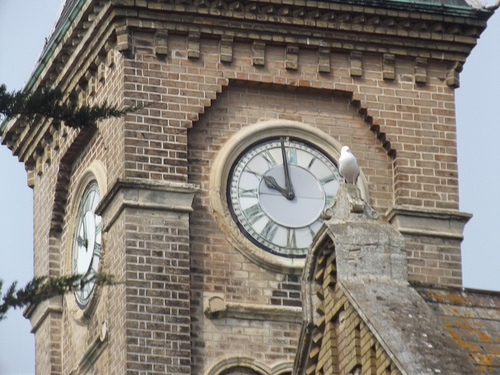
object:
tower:
[3, 0, 500, 375]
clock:
[209, 120, 365, 276]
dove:
[338, 146, 362, 184]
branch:
[0, 83, 155, 129]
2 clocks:
[60, 117, 368, 322]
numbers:
[261, 221, 279, 241]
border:
[1, 0, 101, 124]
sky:
[0, 0, 500, 375]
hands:
[280, 141, 295, 201]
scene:
[0, 1, 499, 372]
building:
[0, 0, 498, 374]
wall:
[187, 78, 395, 370]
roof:
[0, 0, 499, 158]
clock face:
[65, 179, 111, 307]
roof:
[412, 277, 498, 374]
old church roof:
[406, 280, 499, 374]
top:
[1, 0, 500, 187]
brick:
[149, 124, 164, 133]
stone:
[123, 178, 197, 210]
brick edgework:
[303, 19, 318, 27]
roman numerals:
[306, 157, 320, 170]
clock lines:
[229, 184, 239, 189]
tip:
[320, 185, 379, 218]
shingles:
[470, 322, 482, 328]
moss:
[436, 289, 466, 304]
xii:
[283, 147, 301, 162]